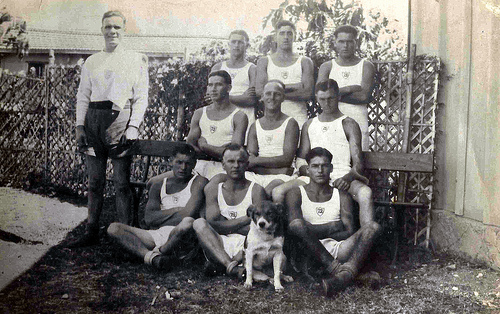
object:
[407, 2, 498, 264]
wall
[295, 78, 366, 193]
man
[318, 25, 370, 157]
man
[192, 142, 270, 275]
man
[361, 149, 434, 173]
wooden plank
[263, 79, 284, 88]
bald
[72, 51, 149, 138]
shirt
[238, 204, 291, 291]
dog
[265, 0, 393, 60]
tree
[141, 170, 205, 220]
tops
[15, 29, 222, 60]
roof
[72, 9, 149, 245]
coach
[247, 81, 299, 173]
member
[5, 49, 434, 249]
fence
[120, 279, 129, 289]
grass grows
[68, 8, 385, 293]
group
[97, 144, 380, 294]
men sitting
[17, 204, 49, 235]
floor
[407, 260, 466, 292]
ground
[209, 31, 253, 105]
man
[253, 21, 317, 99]
man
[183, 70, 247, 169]
man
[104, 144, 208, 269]
man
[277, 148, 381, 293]
man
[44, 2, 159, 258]
man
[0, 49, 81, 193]
fence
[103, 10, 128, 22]
hair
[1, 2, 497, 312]
picture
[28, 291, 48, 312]
grass